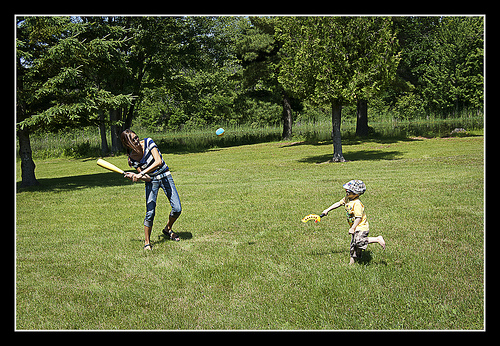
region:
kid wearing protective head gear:
[296, 172, 396, 278]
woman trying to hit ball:
[100, 112, 233, 257]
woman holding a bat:
[97, 115, 187, 247]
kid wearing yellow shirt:
[284, 165, 409, 271]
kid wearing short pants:
[287, 164, 407, 270]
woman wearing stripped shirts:
[82, 107, 197, 257]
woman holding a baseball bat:
[84, 111, 186, 256]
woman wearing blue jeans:
[87, 110, 196, 257]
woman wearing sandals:
[90, 117, 197, 262]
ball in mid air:
[209, 122, 231, 141]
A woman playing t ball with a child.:
[95, 126, 388, 268]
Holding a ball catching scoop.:
[300, 203, 322, 228]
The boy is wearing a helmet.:
[337, 173, 364, 194]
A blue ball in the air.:
[207, 123, 228, 139]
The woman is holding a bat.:
[90, 155, 150, 181]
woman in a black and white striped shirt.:
[127, 136, 169, 176]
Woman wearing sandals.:
[138, 225, 184, 250]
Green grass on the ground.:
[6, 137, 486, 324]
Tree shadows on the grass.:
[13, 127, 419, 188]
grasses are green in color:
[23, 202, 485, 319]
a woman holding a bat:
[95, 127, 177, 252]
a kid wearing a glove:
[300, 178, 385, 269]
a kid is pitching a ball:
[213, 125, 385, 267]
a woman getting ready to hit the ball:
[97, 125, 236, 253]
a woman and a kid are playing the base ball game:
[96, 123, 386, 268]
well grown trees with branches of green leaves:
[0, 38, 485, 180]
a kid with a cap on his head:
[300, 176, 385, 266]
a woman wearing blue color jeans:
[97, 125, 182, 255]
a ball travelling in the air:
[194, 114, 254, 153]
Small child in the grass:
[312, 167, 389, 271]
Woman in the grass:
[77, 100, 229, 272]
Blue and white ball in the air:
[208, 123, 233, 144]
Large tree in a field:
[287, 28, 352, 160]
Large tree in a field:
[349, 69, 383, 151]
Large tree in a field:
[260, 66, 330, 153]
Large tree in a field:
[18, 49, 50, 208]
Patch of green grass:
[47, 259, 131, 326]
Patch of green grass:
[202, 256, 303, 340]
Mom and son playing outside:
[72, 97, 437, 289]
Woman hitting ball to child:
[75, 102, 410, 287]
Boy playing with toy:
[272, 142, 436, 293]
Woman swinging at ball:
[64, 104, 245, 263]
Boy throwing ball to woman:
[89, 107, 431, 300]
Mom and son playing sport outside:
[69, 100, 471, 302]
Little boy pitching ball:
[211, 116, 417, 293]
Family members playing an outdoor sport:
[82, 99, 444, 294]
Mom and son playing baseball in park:
[94, 104, 436, 284]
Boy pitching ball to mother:
[69, 112, 404, 294]